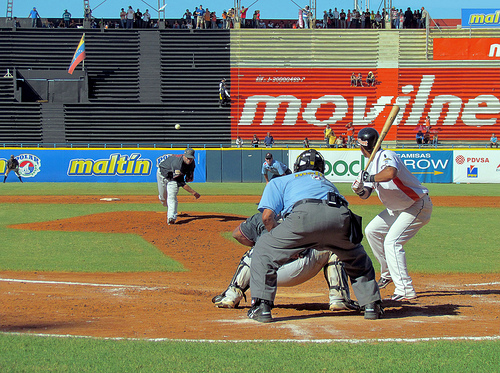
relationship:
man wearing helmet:
[351, 99, 434, 311] [358, 125, 385, 150]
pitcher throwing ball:
[154, 145, 199, 212] [174, 121, 182, 131]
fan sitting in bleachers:
[365, 68, 379, 88] [5, 10, 483, 175]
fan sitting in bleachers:
[354, 65, 365, 84] [5, 10, 483, 175]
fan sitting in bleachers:
[344, 66, 355, 83] [5, 10, 483, 175]